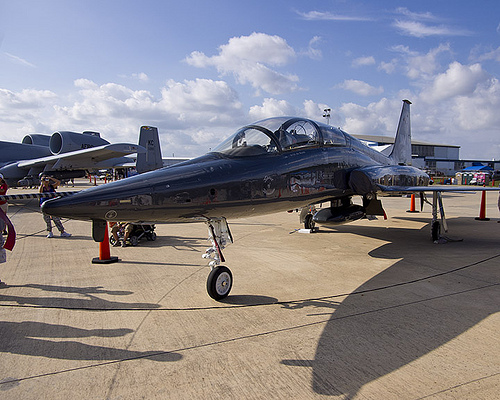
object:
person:
[38, 172, 72, 237]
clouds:
[6, 29, 301, 114]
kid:
[111, 219, 135, 247]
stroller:
[109, 221, 156, 246]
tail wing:
[388, 98, 413, 162]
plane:
[41, 99, 499, 300]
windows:
[412, 145, 434, 155]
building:
[404, 142, 462, 171]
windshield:
[209, 117, 319, 156]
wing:
[382, 184, 500, 192]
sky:
[52, 23, 414, 105]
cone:
[91, 217, 119, 264]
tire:
[206, 266, 234, 302]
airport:
[1, 123, 498, 349]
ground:
[9, 301, 497, 394]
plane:
[127, 302, 498, 399]